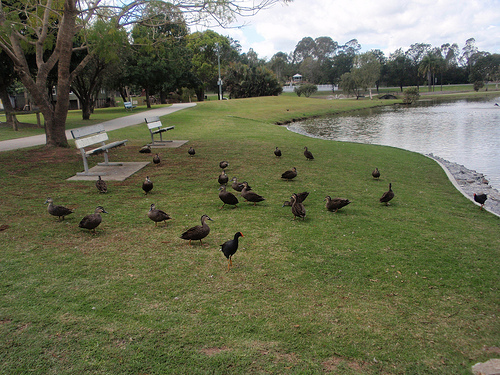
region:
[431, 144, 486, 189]
small waves at edge of water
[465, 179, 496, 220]
black duck standing at edge of grass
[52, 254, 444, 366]
green grass with brown patches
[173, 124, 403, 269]
black ducks standing on green grass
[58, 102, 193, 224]
gray and white park benches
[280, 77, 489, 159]
water pond in a park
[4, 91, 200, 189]
walking path in a green park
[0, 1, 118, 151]
large tree next to the walkway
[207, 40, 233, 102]
light pole in the park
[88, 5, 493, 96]
green trees in the green park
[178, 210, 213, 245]
a duck is on the grass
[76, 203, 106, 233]
a duck is on the grass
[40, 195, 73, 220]
a duck is on the grass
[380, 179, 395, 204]
a duck is near the lake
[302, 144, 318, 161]
a duck is near the lake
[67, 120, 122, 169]
a bench is facing the lake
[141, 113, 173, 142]
a bench is facing the lake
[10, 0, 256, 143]
a tree is behind the benches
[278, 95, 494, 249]
a lake is in a park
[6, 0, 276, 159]
the tree is bare without leaves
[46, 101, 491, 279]
ducks on the grass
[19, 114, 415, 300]
ducks walking on the grass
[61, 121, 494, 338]
ducks walking by the water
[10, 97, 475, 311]
ducks walking in a park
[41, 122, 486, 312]
a park with ducks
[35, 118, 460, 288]
an area with ducks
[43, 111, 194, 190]
two benches on the grass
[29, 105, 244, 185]
two benches in the area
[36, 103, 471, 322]
ducks walking by the benches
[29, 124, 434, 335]
ducks walking during the day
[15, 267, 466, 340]
The grass is green with small patches of dirt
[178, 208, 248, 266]
Black ducks on the grass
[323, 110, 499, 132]
The lake water is calm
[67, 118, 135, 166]
A bench to sit and watch ducks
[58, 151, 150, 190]
A concrete slab for the bench to sit on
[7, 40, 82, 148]
The tree trunck is brown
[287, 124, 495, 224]
The border of the lake and the land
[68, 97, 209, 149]
The sidewalk pathway is clear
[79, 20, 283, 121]
A lot of trees with green leaves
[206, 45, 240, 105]
A steel pole in the park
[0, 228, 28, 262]
black duck on green grass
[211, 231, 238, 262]
black duck on green grass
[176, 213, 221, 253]
black duck on green grass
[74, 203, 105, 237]
black duck on green grass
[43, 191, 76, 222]
black duck on green grass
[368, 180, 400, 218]
black duck on green grass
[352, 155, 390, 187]
black duck on green grass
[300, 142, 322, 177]
black duck on green grass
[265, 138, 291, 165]
black duck on green grass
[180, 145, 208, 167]
black duck on green grass